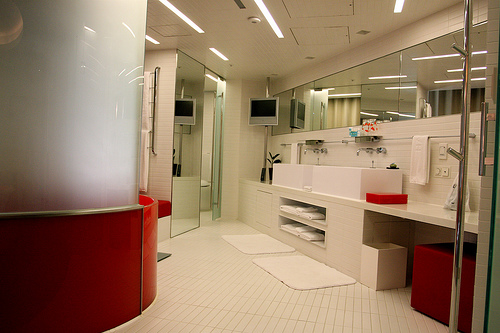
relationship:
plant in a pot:
[266, 143, 286, 165] [265, 162, 277, 184]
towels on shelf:
[279, 202, 327, 220] [281, 208, 324, 237]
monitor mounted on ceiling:
[244, 92, 284, 128] [147, 1, 461, 83]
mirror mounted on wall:
[270, 21, 488, 136] [239, 5, 491, 202]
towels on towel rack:
[142, 67, 161, 196] [149, 56, 160, 163]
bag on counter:
[441, 170, 471, 215] [241, 176, 477, 236]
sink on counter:
[309, 163, 403, 201] [241, 176, 477, 236]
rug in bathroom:
[250, 249, 356, 295] [2, 2, 494, 329]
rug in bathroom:
[221, 231, 295, 256] [2, 2, 494, 329]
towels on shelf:
[273, 200, 320, 245] [279, 225, 325, 252]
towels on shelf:
[281, 202, 327, 219] [277, 207, 329, 232]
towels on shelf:
[279, 223, 325, 245] [277, 207, 329, 232]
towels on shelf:
[406, 134, 431, 186] [277, 207, 329, 232]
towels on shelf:
[141, 69, 151, 196] [277, 207, 329, 232]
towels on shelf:
[281, 202, 327, 219] [279, 225, 325, 252]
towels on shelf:
[279, 223, 325, 245] [279, 225, 325, 252]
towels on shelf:
[406, 134, 431, 186] [279, 225, 325, 252]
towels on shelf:
[141, 69, 151, 196] [279, 225, 325, 252]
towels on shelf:
[281, 202, 327, 219] [348, 130, 383, 141]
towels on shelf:
[279, 223, 325, 245] [348, 130, 383, 141]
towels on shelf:
[406, 134, 431, 186] [348, 130, 383, 141]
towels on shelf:
[141, 69, 151, 196] [348, 130, 383, 141]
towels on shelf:
[281, 202, 327, 219] [301, 136, 323, 145]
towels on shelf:
[279, 223, 325, 245] [301, 136, 323, 145]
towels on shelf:
[406, 134, 431, 186] [301, 136, 323, 145]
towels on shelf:
[141, 69, 151, 196] [301, 136, 323, 145]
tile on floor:
[326, 294, 340, 306] [101, 218, 462, 331]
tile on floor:
[255, 299, 272, 316] [101, 218, 462, 331]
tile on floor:
[156, 319, 177, 331] [101, 218, 462, 331]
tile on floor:
[360, 312, 369, 331] [101, 218, 462, 331]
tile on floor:
[313, 320, 323, 331] [101, 218, 462, 331]